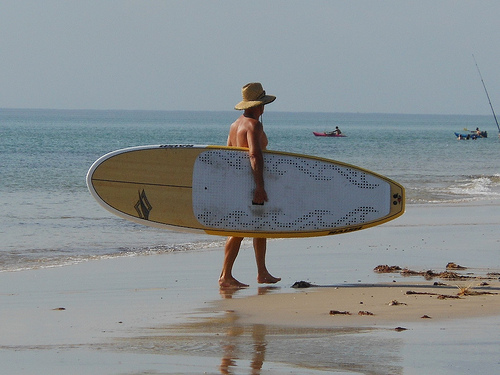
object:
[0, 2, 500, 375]
photo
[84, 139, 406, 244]
board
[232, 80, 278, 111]
straw hat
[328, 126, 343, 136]
woman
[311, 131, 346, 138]
jet ski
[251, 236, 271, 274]
leg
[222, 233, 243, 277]
leg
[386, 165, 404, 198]
ground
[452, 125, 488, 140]
boat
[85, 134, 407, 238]
surfboard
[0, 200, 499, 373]
coast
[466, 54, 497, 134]
pole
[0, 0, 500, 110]
sky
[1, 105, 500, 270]
water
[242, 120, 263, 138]
shoulder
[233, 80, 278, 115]
head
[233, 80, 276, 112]
hat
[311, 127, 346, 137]
ski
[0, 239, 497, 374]
ground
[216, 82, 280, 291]
man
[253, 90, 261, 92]
straw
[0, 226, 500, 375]
sand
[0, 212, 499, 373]
beach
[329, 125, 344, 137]
man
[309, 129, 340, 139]
kayak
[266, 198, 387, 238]
design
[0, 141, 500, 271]
ocean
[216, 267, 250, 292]
foot